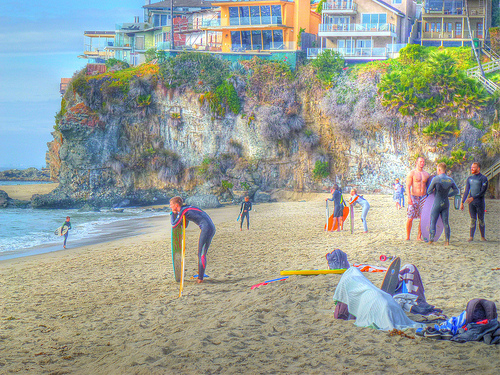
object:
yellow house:
[134, 1, 497, 139]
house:
[199, 0, 320, 70]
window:
[228, 7, 238, 26]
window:
[238, 7, 247, 24]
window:
[250, 5, 260, 25]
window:
[260, 5, 270, 25]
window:
[271, 5, 280, 23]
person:
[324, 184, 346, 234]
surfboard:
[325, 206, 350, 232]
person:
[166, 193, 218, 285]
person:
[425, 162, 460, 245]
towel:
[334, 265, 425, 332]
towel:
[434, 311, 468, 333]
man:
[61, 216, 73, 250]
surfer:
[59, 212, 71, 249]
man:
[399, 149, 438, 249]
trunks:
[408, 198, 428, 220]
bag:
[326, 248, 348, 270]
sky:
[0, 0, 144, 166]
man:
[334, 259, 498, 351]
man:
[416, 160, 486, 255]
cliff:
[31, 63, 498, 199]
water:
[0, 207, 116, 252]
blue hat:
[461, 53, 496, 97]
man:
[144, 197, 211, 268]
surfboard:
[148, 206, 200, 278]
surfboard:
[169, 204, 184, 281]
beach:
[0, 188, 499, 372]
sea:
[0, 204, 212, 268]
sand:
[32, 279, 342, 366]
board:
[418, 189, 450, 248]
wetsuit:
[468, 178, 489, 237]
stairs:
[417, 36, 485, 91]